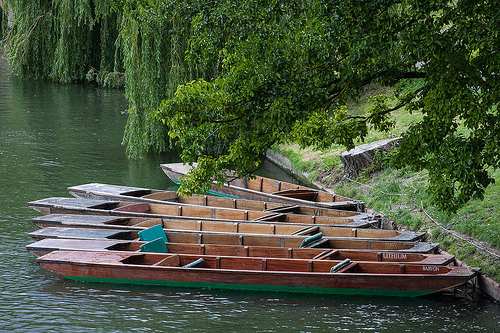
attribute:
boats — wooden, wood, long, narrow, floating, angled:
[156, 152, 369, 213]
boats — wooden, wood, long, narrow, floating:
[64, 176, 385, 225]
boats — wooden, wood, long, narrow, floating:
[24, 190, 385, 232]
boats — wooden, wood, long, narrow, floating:
[28, 208, 426, 243]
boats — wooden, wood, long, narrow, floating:
[21, 222, 440, 255]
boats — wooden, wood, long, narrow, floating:
[20, 233, 460, 268]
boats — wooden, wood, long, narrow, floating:
[28, 248, 484, 298]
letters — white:
[418, 263, 443, 275]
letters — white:
[380, 249, 412, 261]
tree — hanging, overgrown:
[116, 2, 232, 162]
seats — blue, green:
[141, 236, 174, 256]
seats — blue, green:
[135, 220, 173, 246]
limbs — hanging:
[299, 80, 425, 140]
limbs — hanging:
[147, 65, 425, 198]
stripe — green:
[61, 272, 438, 300]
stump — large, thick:
[333, 133, 411, 175]